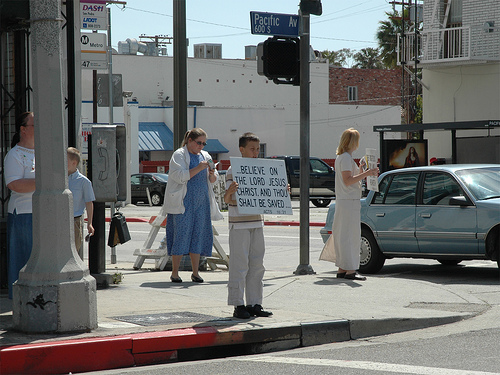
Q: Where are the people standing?
A: On the sidewalk.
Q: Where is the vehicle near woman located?
A: On the corner.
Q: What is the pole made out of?
A: Metal.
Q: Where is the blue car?
A: On the street.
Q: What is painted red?
A: The curb.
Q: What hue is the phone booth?
A: Silver.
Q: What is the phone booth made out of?
A: Metal.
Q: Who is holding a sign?
A: The woman.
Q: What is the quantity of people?
A: Five.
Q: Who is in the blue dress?
A: The woman.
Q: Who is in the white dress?
A: The woman.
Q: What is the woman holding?
A: A sign.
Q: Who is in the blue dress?
A: The woman.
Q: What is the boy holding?
A: A sign.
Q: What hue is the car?
A: Light blue.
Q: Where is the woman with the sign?
A: On the street corner.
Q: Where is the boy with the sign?
A: On the street corner.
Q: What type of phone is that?
A: Coin operated phone.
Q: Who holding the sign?
A: A boy.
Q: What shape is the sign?
A: Rectangle.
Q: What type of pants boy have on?
A: Khakis.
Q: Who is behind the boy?
A: A lady.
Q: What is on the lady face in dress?
A: Shades.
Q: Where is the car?
A: Corner of street.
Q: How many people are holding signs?
A: Two.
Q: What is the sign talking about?
A: Jesus.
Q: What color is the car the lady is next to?
A: Blue.